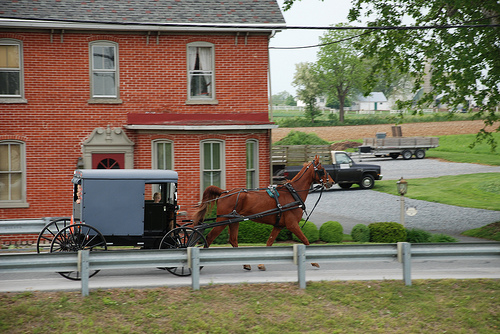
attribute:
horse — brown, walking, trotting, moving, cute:
[193, 154, 336, 269]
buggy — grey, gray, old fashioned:
[38, 169, 208, 281]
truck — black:
[276, 145, 383, 190]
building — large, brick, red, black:
[0, 1, 288, 248]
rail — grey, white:
[2, 242, 499, 297]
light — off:
[396, 177, 409, 229]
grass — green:
[375, 173, 500, 214]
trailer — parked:
[355, 137, 438, 160]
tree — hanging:
[347, 3, 500, 155]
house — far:
[355, 92, 388, 114]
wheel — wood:
[160, 225, 210, 277]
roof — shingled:
[0, 1, 286, 26]